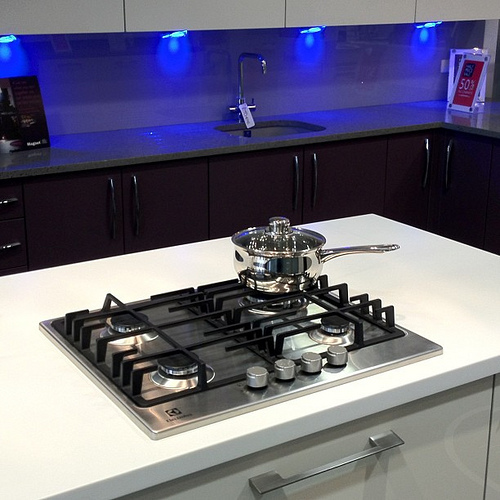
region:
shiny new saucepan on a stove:
[229, 215, 400, 296]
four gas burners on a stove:
[38, 262, 445, 439]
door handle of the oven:
[248, 423, 406, 495]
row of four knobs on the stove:
[243, 341, 349, 392]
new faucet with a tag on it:
[226, 48, 269, 123]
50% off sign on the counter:
[446, 50, 491, 119]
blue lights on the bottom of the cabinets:
[0, 19, 444, 44]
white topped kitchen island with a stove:
[1, 212, 499, 499]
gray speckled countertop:
[0, 99, 498, 180]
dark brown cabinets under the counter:
[1, 123, 499, 275]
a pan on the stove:
[179, 205, 364, 323]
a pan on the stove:
[185, 179, 336, 289]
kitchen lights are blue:
[21, 31, 452, 76]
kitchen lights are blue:
[137, 8, 324, 76]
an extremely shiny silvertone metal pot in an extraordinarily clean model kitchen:
[222, 214, 409, 306]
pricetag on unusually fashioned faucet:
[234, 99, 259, 131]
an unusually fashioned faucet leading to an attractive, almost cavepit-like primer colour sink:
[211, 46, 339, 146]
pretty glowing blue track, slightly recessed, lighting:
[2, 20, 462, 82]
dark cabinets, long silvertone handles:
[0, 128, 469, 283]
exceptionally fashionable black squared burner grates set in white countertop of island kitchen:
[41, 260, 411, 405]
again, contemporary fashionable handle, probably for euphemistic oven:
[227, 421, 417, 496]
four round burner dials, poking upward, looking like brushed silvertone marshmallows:
[236, 340, 357, 396]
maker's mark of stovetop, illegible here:
[151, 394, 202, 433]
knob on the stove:
[331, 345, 352, 368]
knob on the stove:
[304, 355, 319, 380]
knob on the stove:
[271, 350, 298, 377]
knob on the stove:
[243, 368, 267, 392]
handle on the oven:
[237, 436, 429, 496]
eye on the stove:
[164, 349, 204, 386]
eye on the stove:
[102, 306, 156, 340]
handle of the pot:
[329, 236, 410, 263]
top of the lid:
[266, 213, 298, 243]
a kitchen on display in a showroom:
[6, 4, 481, 417]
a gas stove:
[46, 245, 455, 439]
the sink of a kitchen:
[218, 43, 323, 149]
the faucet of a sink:
[228, 48, 268, 129]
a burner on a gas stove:
[93, 303, 160, 343]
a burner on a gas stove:
[151, 336, 204, 384]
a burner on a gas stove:
[304, 304, 352, 341]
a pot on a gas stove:
[231, 201, 402, 323]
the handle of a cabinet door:
[106, 173, 122, 248]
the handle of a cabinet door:
[128, 170, 148, 237]